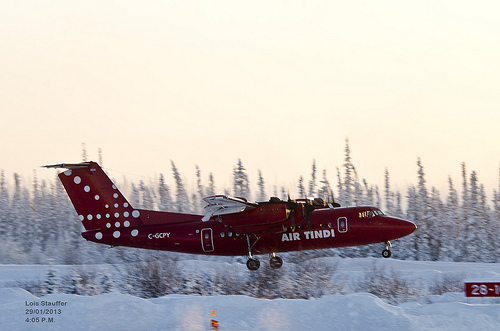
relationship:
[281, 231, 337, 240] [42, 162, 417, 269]
wording on side of airplane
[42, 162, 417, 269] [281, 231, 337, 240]
airplane has wording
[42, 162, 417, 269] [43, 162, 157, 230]
airplane has tail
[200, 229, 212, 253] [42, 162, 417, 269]
door on airplane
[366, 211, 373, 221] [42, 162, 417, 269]
pilot inside airplane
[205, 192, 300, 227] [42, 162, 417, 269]
wing on side of airplane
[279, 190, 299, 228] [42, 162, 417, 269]
propeller on airplane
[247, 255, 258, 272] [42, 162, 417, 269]
wheels under airplane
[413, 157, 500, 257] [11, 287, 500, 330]
trees covered with snow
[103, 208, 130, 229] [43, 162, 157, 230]
dots on tail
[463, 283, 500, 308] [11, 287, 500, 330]
sign in snow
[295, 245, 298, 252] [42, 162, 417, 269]
light under airplane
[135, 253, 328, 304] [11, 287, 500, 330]
bushes covered with snow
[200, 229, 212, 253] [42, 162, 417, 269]
door on side of airplane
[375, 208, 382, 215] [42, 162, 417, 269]
windshield on front of airplane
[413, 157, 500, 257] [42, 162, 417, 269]
trees behind airplane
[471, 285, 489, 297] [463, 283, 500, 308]
number on sign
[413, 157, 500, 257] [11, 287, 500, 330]
trees covered snow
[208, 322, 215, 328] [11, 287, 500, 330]
flag in snow